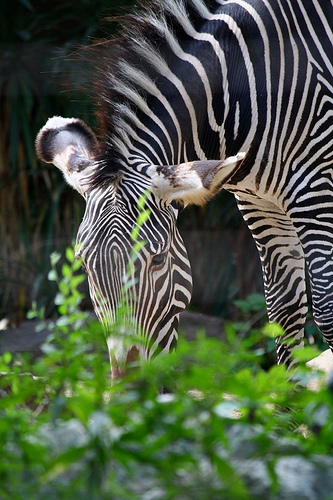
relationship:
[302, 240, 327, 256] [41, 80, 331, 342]
black and white striped zebra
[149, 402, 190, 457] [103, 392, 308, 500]
leaves on brown branches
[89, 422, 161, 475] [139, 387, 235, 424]
leaves on brown branches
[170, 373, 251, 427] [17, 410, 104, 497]
leaves on brown branches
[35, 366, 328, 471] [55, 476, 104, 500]
plants are green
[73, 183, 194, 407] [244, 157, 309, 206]
head of zebra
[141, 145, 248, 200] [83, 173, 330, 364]
ear of zebra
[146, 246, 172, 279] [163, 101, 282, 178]
eye of zebra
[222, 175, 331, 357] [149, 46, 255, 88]
front legs of zebra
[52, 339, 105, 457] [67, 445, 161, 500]
these are leaves on a branch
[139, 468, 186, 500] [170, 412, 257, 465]
these are leaves on a branch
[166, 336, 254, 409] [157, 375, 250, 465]
these are leaves on a branch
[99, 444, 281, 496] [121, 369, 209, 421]
these are leaves on a branch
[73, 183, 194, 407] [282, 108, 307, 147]
head of a zebra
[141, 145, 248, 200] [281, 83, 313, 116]
ear of a zebra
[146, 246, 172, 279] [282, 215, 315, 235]
eye of a zebra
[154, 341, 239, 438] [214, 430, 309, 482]
leaves of a tree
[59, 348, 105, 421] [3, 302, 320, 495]
green plants growing in field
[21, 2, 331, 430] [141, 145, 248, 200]
zebra with ear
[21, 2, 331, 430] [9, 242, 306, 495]
zebra hiding behind leaves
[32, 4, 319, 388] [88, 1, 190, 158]
striped mammal with mane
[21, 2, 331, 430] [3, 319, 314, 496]
zebra feeding on a yard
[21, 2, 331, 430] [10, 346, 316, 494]
zebra eating plants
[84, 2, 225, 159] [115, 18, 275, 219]
mane on neck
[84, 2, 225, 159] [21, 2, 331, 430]
mane on zebra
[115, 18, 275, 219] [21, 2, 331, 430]
neck on zebra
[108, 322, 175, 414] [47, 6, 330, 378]
muzzle on zebra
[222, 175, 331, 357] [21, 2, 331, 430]
front legs on zebra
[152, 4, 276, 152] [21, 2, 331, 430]
stripes on zebra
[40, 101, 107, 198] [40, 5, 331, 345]
ear on zebra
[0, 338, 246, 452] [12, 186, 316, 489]
leaves on plant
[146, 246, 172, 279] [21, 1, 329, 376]
eye on zebra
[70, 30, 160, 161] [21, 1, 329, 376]
hair on back of zebra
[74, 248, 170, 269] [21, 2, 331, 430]
eyes on zebra